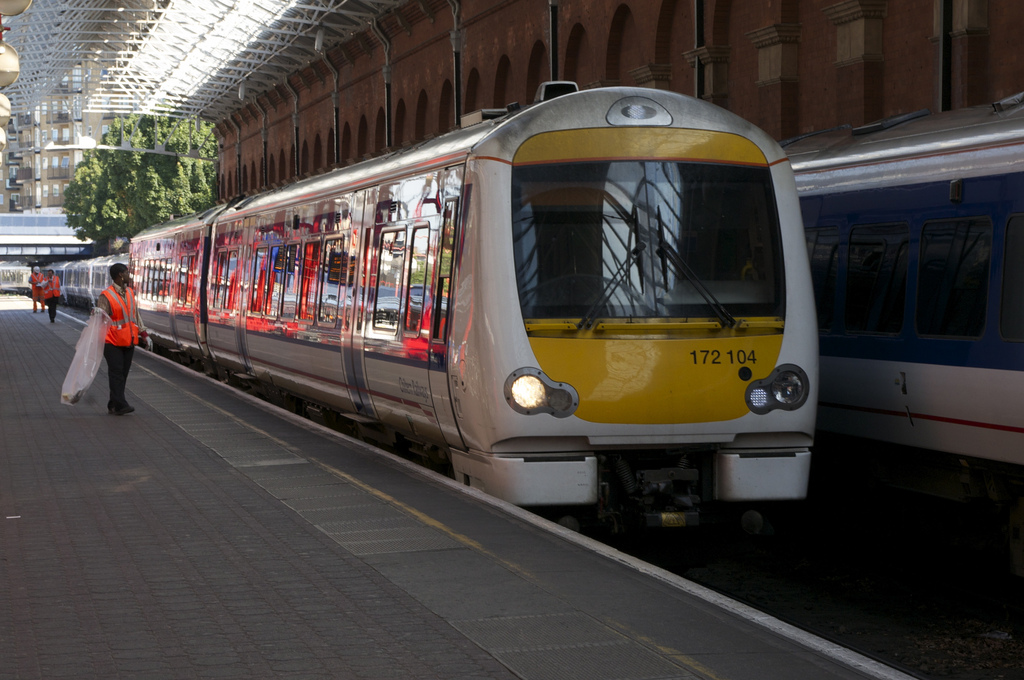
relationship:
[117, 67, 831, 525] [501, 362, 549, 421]
train has headlight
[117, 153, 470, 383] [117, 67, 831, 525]
reflection on train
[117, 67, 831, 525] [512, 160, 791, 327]
train has windshield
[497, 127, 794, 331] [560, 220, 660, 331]
windshield has wiper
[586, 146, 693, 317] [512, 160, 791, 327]
reflection on windshield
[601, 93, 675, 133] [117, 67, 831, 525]
headlight on train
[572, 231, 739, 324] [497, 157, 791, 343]
wipers on window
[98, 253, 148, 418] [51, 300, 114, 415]
worker carry bag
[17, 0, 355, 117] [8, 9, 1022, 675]
roof in station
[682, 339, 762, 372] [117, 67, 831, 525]
number on train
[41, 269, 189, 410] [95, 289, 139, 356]
man in safety vest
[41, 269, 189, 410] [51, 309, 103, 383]
man holding bag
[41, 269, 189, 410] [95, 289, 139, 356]
man in a safety vest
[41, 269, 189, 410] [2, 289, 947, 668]
man standing on station platform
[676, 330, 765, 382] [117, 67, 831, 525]
identification numbers displayed on train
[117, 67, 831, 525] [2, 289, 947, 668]
train at station platform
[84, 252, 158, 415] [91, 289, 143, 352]
worker wearing vest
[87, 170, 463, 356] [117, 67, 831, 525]
windows along side of train